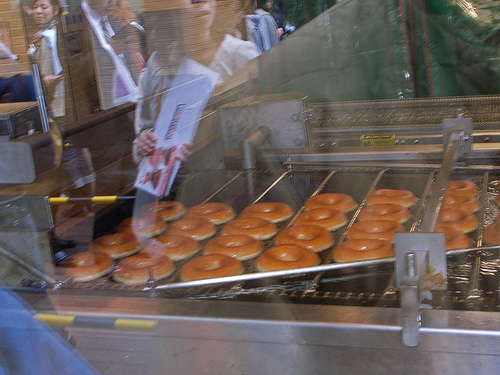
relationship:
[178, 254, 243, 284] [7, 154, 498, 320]
donut on conveyer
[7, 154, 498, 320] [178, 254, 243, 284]
conveyer for donut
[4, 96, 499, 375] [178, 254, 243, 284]
machine makes a donut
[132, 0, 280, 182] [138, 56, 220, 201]
woman has a box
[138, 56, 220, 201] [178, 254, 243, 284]
box for donut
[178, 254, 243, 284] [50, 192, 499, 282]
donut on tray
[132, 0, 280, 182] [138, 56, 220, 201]
person holding box